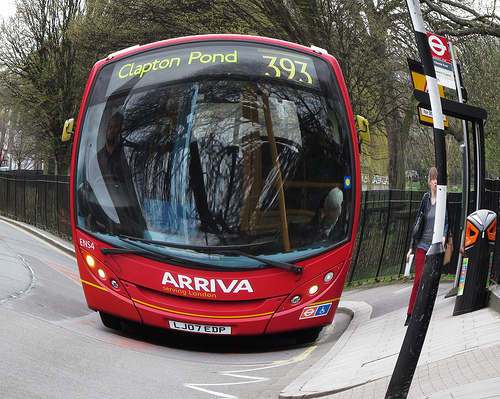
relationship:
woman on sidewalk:
[396, 158, 454, 329] [274, 275, 484, 393]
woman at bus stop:
[396, 158, 454, 329] [399, 37, 474, 317]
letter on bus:
[117, 60, 128, 79] [61, 30, 376, 356]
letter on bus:
[125, 61, 132, 73] [61, 30, 376, 356]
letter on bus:
[134, 63, 143, 75] [61, 30, 376, 356]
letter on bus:
[139, 60, 151, 76] [61, 30, 376, 356]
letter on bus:
[149, 55, 159, 69] [61, 30, 376, 356]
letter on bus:
[159, 58, 166, 70] [61, 30, 376, 356]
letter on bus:
[168, 56, 179, 71] [61, 30, 376, 356]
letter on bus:
[186, 48, 200, 68] [61, 30, 376, 356]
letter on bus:
[198, 50, 209, 65] [61, 30, 376, 356]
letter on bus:
[210, 51, 224, 66] [61, 30, 376, 356]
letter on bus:
[177, 50, 221, 70] [61, 30, 376, 356]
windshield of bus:
[75, 77, 355, 268] [61, 30, 376, 356]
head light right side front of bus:
[305, 275, 336, 292] [77, 43, 344, 336]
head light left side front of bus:
[305, 275, 336, 292] [77, 43, 344, 336]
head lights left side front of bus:
[76, 254, 358, 311] [27, 27, 383, 356]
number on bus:
[261, 51, 313, 89] [61, 30, 376, 356]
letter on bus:
[206, 291, 216, 301] [81, 34, 337, 347]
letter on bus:
[223, 42, 242, 79] [61, 30, 376, 356]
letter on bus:
[168, 56, 184, 70] [61, 30, 376, 356]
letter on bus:
[198, 52, 213, 66] [60, 40, 397, 341]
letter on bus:
[210, 49, 229, 66] [56, 24, 349, 337]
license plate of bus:
[168, 320, 230, 335] [61, 30, 376, 356]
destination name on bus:
[114, 49, 241, 78] [69, 37, 361, 331]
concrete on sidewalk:
[332, 311, 478, 380] [343, 280, 484, 387]